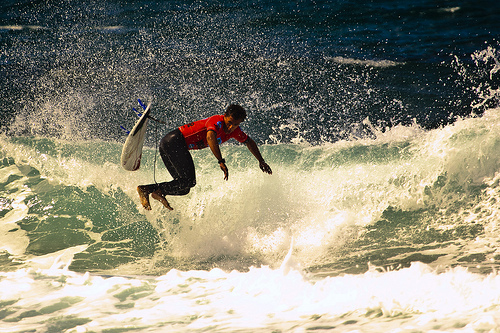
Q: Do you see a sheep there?
A: Yes, there is a sheep.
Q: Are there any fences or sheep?
A: Yes, there is a sheep.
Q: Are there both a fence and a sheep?
A: No, there is a sheep but no fences.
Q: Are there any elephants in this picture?
A: No, there are no elephants.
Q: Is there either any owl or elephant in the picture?
A: No, there are no elephants or owls.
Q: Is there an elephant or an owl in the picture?
A: No, there are no elephants or owls.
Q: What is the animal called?
A: The animal is a sheep.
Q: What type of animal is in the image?
A: The animal is a sheep.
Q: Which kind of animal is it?
A: The animal is a sheep.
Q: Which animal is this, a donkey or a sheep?
A: That is a sheep.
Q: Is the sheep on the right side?
A: Yes, the sheep is on the right of the image.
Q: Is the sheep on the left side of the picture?
A: No, the sheep is on the right of the image.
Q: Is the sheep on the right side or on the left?
A: The sheep is on the right of the image.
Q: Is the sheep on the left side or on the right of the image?
A: The sheep is on the right of the image.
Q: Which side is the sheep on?
A: The sheep is on the right of the image.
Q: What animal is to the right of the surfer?
A: The animal is a sheep.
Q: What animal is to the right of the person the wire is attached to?
A: The animal is a sheep.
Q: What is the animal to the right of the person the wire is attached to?
A: The animal is a sheep.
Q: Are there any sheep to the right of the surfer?
A: Yes, there is a sheep to the right of the surfer.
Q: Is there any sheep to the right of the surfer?
A: Yes, there is a sheep to the right of the surfer.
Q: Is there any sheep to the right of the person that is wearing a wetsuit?
A: Yes, there is a sheep to the right of the surfer.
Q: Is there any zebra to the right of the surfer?
A: No, there is a sheep to the right of the surfer.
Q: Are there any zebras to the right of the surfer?
A: No, there is a sheep to the right of the surfer.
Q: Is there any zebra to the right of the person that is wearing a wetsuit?
A: No, there is a sheep to the right of the surfer.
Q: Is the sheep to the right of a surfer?
A: Yes, the sheep is to the right of a surfer.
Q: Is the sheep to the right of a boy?
A: No, the sheep is to the right of a surfer.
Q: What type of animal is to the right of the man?
A: The animal is a sheep.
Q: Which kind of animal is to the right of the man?
A: The animal is a sheep.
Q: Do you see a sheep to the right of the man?
A: Yes, there is a sheep to the right of the man.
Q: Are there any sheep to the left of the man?
A: No, the sheep is to the right of the man.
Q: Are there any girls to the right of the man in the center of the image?
A: No, there is a sheep to the right of the man.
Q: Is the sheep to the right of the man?
A: Yes, the sheep is to the right of the man.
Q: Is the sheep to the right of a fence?
A: No, the sheep is to the right of the man.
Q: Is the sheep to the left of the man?
A: No, the sheep is to the right of the man.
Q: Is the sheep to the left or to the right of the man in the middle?
A: The sheep is to the right of the man.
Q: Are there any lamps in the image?
A: No, there are no lamps.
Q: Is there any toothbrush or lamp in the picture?
A: No, there are no lamps or toothbrushes.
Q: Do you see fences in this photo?
A: No, there are no fences.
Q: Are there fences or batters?
A: No, there are no fences or batters.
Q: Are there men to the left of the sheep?
A: Yes, there is a man to the left of the sheep.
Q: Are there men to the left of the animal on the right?
A: Yes, there is a man to the left of the sheep.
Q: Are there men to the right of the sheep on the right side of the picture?
A: No, the man is to the left of the sheep.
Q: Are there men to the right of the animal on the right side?
A: No, the man is to the left of the sheep.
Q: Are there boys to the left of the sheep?
A: No, there is a man to the left of the sheep.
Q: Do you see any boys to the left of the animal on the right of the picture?
A: No, there is a man to the left of the sheep.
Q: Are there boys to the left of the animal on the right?
A: No, there is a man to the left of the sheep.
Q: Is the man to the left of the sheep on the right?
A: Yes, the man is to the left of the sheep.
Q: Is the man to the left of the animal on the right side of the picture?
A: Yes, the man is to the left of the sheep.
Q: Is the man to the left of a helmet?
A: No, the man is to the left of the sheep.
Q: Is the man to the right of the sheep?
A: No, the man is to the left of the sheep.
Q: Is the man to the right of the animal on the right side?
A: No, the man is to the left of the sheep.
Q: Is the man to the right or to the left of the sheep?
A: The man is to the left of the sheep.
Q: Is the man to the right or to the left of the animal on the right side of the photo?
A: The man is to the left of the sheep.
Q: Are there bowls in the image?
A: No, there are no bowls.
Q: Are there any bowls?
A: No, there are no bowls.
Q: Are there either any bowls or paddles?
A: No, there are no bowls or paddles.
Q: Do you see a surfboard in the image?
A: Yes, there is a surfboard.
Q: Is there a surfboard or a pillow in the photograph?
A: Yes, there is a surfboard.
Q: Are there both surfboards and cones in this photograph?
A: No, there is a surfboard but no cones.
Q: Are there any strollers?
A: No, there are no strollers.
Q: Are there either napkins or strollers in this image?
A: No, there are no strollers or napkins.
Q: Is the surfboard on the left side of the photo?
A: Yes, the surfboard is on the left of the image.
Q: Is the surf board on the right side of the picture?
A: No, the surf board is on the left of the image.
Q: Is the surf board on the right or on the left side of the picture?
A: The surf board is on the left of the image.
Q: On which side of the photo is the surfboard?
A: The surfboard is on the left of the image.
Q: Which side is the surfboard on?
A: The surfboard is on the left of the image.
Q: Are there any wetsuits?
A: Yes, there is a wetsuit.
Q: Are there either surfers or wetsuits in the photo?
A: Yes, there is a wetsuit.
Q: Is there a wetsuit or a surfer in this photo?
A: Yes, there is a wetsuit.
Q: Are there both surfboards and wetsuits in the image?
A: Yes, there are both a wetsuit and a surfboard.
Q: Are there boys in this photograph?
A: No, there are no boys.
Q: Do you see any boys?
A: No, there are no boys.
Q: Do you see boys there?
A: No, there are no boys.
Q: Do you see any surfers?
A: Yes, there is a surfer.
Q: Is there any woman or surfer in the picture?
A: Yes, there is a surfer.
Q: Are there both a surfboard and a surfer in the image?
A: Yes, there are both a surfer and a surfboard.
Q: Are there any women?
A: No, there are no women.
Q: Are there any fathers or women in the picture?
A: No, there are no women or fathers.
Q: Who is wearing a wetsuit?
A: The surfer is wearing a wetsuit.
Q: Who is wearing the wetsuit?
A: The surfer is wearing a wetsuit.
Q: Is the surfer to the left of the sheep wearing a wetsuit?
A: Yes, the surfer is wearing a wetsuit.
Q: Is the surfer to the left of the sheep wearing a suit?
A: No, the surfer is wearing a wetsuit.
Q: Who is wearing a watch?
A: The surfer is wearing a watch.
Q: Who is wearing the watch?
A: The surfer is wearing a watch.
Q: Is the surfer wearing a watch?
A: Yes, the surfer is wearing a watch.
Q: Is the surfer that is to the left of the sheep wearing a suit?
A: No, the surfer is wearing a watch.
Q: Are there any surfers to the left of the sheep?
A: Yes, there is a surfer to the left of the sheep.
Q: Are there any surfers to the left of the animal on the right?
A: Yes, there is a surfer to the left of the sheep.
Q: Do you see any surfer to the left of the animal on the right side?
A: Yes, there is a surfer to the left of the sheep.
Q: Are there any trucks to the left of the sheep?
A: No, there is a surfer to the left of the sheep.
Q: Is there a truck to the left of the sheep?
A: No, there is a surfer to the left of the sheep.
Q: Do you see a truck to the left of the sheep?
A: No, there is a surfer to the left of the sheep.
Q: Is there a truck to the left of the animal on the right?
A: No, there is a surfer to the left of the sheep.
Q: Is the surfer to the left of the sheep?
A: Yes, the surfer is to the left of the sheep.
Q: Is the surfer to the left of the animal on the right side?
A: Yes, the surfer is to the left of the sheep.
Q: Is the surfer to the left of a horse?
A: No, the surfer is to the left of the sheep.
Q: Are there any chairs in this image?
A: No, there are no chairs.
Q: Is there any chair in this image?
A: No, there are no chairs.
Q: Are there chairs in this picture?
A: No, there are no chairs.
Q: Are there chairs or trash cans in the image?
A: No, there are no chairs or trash cans.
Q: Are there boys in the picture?
A: No, there are no boys.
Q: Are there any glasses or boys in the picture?
A: No, there are no boys or glasses.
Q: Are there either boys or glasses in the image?
A: No, there are no boys or glasses.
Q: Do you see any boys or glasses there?
A: No, there are no boys or glasses.